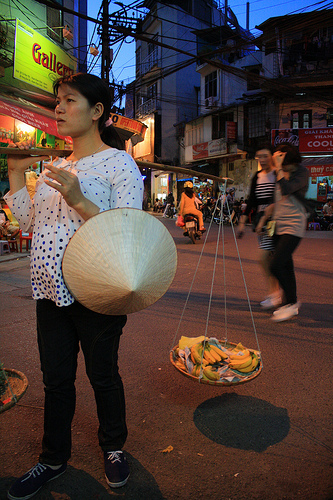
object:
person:
[264, 137, 308, 323]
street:
[1, 218, 332, 499]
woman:
[6, 73, 143, 498]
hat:
[60, 207, 179, 316]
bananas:
[229, 354, 256, 369]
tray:
[169, 340, 264, 387]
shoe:
[102, 449, 131, 489]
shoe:
[5, 464, 69, 500]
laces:
[18, 474, 34, 484]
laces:
[111, 458, 118, 464]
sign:
[13, 19, 79, 96]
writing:
[32, 43, 74, 80]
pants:
[35, 299, 127, 466]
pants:
[267, 235, 303, 304]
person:
[176, 181, 206, 233]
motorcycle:
[182, 214, 201, 246]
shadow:
[191, 394, 290, 452]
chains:
[170, 191, 222, 347]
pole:
[0, 148, 235, 186]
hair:
[53, 73, 125, 151]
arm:
[42, 159, 144, 221]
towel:
[179, 335, 197, 348]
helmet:
[183, 181, 193, 189]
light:
[60, 27, 75, 43]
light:
[90, 44, 98, 57]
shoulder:
[42, 156, 66, 168]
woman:
[234, 142, 283, 308]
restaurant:
[1, 85, 73, 254]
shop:
[269, 125, 333, 230]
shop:
[180, 138, 264, 222]